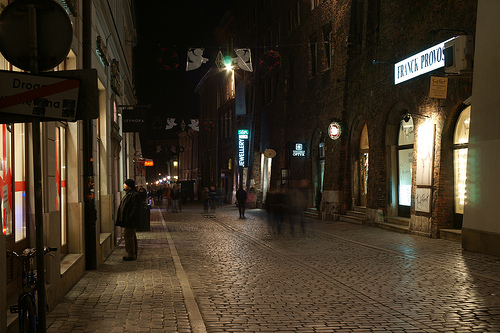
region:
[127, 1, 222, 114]
dark sky of night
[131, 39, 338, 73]
banners hanging on line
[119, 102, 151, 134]
black sign on pole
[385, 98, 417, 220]
arched shape of doorway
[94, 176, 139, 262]
man looing in window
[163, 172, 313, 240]
people walking on street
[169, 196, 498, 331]
surface of cobblestone street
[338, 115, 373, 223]
steps in front of doorway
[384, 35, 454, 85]
glowing white rectangle sign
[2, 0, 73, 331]
roun sign on pole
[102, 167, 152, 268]
THIS MAN IS STANDING ON THE SIDWALK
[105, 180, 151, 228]
THIS MAN IS WEARING A BIG JACKET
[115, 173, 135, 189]
THIS MAN'S HAT IS BLACK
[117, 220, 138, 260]
THIS MAN'S PANTS ARE TAN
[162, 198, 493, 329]
THIS IS A COBBLESTONE STREET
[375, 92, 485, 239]
THESE WINDOWS ARE ARCHED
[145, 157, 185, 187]
THESE LIGHTS ARE BRIGHT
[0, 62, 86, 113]
THIS IS A SIGN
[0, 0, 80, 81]
THIS IS A ROUND SIGN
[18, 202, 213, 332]
THIS IS A SIDEWALK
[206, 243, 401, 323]
cobblestone street at night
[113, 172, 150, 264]
person looking into a window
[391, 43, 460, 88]
lighted sign on a building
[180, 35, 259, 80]
christmas decorations above the street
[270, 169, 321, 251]
people walking on the street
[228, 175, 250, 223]
person on the street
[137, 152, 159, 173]
red light on a building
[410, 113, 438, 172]
light on a building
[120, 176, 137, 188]
hat on a persons head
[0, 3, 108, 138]
sign on a building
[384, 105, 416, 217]
this is the door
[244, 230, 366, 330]
this is the road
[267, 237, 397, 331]
the road is tarmacked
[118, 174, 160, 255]
this is a man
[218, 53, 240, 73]
this is a light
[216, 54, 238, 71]
the light is on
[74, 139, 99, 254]
this is a pole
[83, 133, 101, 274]
the pole is black in color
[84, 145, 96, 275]
the pole is straight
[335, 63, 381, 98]
the wall is old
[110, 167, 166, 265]
Person looking at store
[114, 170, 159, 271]
One person on the sidewalk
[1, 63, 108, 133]
Sign has a red line through it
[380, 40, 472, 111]
"Frima Promo"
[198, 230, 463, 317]
Floor is made of pebbles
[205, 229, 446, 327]
Floor is light brown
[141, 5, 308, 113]
It is nighttime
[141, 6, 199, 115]
The sky is pitch black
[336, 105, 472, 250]
The windows are upside down U's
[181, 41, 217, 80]
White angel by the signs